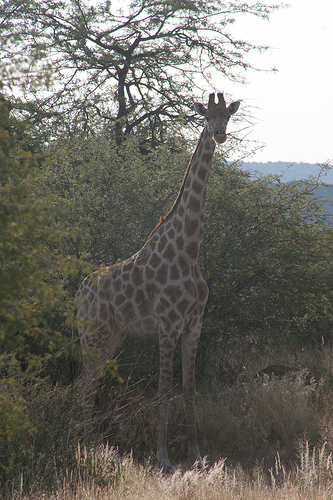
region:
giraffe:
[64, 86, 232, 399]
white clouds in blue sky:
[261, 104, 294, 138]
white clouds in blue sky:
[274, 64, 301, 92]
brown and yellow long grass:
[230, 358, 275, 382]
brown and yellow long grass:
[100, 464, 146, 495]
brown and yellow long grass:
[203, 425, 251, 468]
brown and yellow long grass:
[254, 456, 307, 492]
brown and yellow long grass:
[268, 352, 302, 395]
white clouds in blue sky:
[263, 92, 306, 143]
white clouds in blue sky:
[273, 75, 310, 112]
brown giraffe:
[32, 81, 241, 420]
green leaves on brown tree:
[241, 237, 282, 277]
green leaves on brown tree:
[243, 284, 265, 306]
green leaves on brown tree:
[260, 269, 299, 310]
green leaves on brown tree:
[38, 214, 84, 235]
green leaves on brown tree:
[64, 159, 103, 185]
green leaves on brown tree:
[37, 252, 75, 305]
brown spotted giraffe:
[79, 87, 228, 443]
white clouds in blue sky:
[263, 109, 299, 134]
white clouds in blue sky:
[269, 51, 311, 78]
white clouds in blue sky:
[274, 118, 310, 144]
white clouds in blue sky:
[274, 70, 303, 87]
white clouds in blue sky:
[284, 94, 324, 121]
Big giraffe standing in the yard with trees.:
[194, 233, 218, 298]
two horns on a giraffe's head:
[208, 93, 226, 103]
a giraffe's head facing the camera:
[191, 90, 243, 144]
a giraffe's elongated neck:
[167, 139, 214, 227]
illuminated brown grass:
[26, 442, 331, 498]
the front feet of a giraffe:
[155, 447, 205, 471]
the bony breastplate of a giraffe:
[182, 272, 208, 311]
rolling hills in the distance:
[224, 157, 332, 227]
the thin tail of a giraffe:
[62, 309, 78, 358]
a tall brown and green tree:
[1, 0, 281, 164]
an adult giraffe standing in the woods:
[73, 91, 241, 476]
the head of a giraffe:
[176, 91, 245, 156]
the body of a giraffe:
[72, 279, 211, 352]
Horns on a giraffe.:
[208, 92, 224, 106]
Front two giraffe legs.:
[155, 316, 203, 474]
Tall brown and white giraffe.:
[74, 92, 240, 471]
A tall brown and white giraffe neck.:
[157, 125, 215, 262]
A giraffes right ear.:
[191, 101, 207, 114]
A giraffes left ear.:
[227, 101, 241, 113]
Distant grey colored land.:
[222, 158, 331, 184]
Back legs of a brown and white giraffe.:
[75, 309, 124, 430]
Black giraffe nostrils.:
[213, 128, 225, 134]